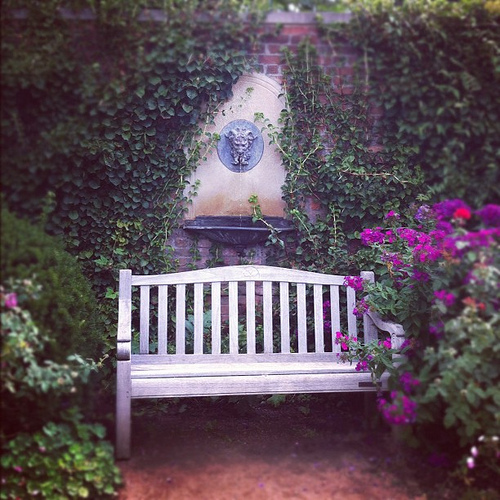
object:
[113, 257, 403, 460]
rest area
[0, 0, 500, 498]
botanical garden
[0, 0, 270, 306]
plants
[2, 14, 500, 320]
wall